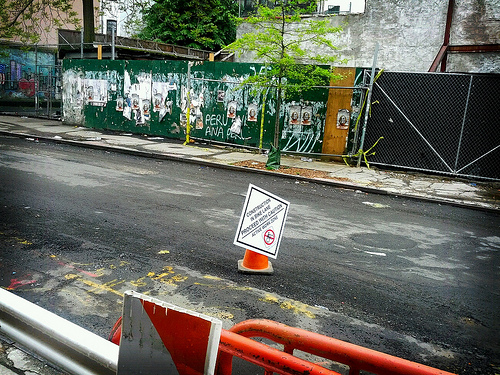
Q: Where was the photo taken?
A: It was taken at the road.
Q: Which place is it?
A: It is a road.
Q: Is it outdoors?
A: Yes, it is outdoors.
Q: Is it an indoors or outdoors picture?
A: It is outdoors.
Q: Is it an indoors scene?
A: No, it is outdoors.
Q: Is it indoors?
A: No, it is outdoors.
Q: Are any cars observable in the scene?
A: No, there are no cars.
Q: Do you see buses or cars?
A: No, there are no cars or buses.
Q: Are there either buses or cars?
A: No, there are no cars or buses.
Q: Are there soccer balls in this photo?
A: No, there are no soccer balls.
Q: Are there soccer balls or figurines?
A: No, there are no soccer balls or figurines.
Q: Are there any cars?
A: No, there are no cars.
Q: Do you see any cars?
A: No, there are no cars.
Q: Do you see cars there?
A: No, there are no cars.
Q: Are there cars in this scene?
A: No, there are no cars.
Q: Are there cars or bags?
A: No, there are no cars or bags.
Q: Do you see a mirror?
A: No, there are no mirrors.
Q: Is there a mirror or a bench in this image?
A: No, there are no mirrors or benches.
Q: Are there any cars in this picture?
A: No, there are no cars.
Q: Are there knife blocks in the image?
A: No, there are no knife blocks.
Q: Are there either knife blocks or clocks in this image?
A: No, there are no knife blocks or clocks.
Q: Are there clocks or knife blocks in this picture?
A: No, there are no knife blocks or clocks.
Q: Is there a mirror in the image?
A: No, there are no mirrors.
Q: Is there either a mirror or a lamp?
A: No, there are no mirrors or lamps.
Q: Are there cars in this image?
A: No, there are no cars.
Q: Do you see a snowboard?
A: No, there are no snowboards.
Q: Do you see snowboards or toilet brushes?
A: No, there are no snowboards or toilet brushes.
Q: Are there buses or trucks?
A: No, there are no buses or trucks.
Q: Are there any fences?
A: Yes, there is a fence.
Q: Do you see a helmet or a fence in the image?
A: Yes, there is a fence.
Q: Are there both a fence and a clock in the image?
A: No, there is a fence but no clocks.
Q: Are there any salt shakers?
A: No, there are no salt shakers.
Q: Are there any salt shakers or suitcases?
A: No, there are no salt shakers or suitcases.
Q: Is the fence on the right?
A: Yes, the fence is on the right of the image.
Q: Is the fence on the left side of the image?
A: No, the fence is on the right of the image.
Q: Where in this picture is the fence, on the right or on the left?
A: The fence is on the right of the image.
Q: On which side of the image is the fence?
A: The fence is on the right of the image.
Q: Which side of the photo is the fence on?
A: The fence is on the right of the image.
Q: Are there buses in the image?
A: No, there are no buses.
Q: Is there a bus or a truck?
A: No, there are no buses or trucks.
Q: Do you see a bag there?
A: No, there are no bags.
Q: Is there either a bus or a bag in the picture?
A: No, there are no bags or buses.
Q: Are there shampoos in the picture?
A: No, there are no shampoos.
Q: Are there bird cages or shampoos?
A: No, there are no shampoos or bird cages.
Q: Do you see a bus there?
A: No, there are no buses.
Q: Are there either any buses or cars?
A: No, there are no buses or cars.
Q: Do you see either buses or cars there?
A: No, there are no buses or cars.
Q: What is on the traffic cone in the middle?
A: The sign is on the safety cone.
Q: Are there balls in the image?
A: No, there are no balls.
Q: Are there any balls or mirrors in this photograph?
A: No, there are no balls or mirrors.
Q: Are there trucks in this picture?
A: No, there are no trucks.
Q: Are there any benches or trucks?
A: No, there are no trucks or benches.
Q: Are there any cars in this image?
A: No, there are no cars.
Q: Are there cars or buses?
A: No, there are no cars or buses.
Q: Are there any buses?
A: No, there are no buses.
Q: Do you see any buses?
A: No, there are no buses.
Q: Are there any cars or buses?
A: No, there are no buses or cars.